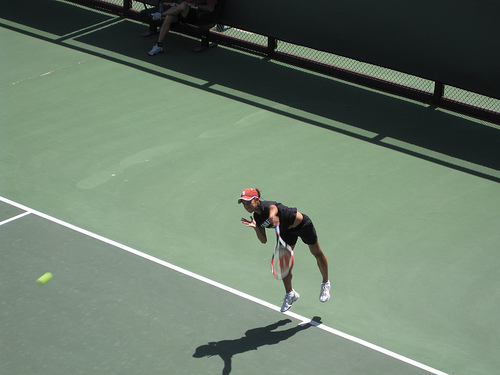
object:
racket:
[270, 226, 294, 279]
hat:
[238, 188, 258, 203]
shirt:
[253, 201, 297, 229]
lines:
[0, 195, 447, 375]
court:
[0, 81, 499, 373]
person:
[146, 2, 210, 56]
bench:
[140, 9, 217, 53]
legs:
[158, 14, 172, 43]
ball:
[35, 272, 52, 284]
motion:
[69, 255, 132, 280]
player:
[237, 188, 329, 312]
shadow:
[191, 40, 396, 88]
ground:
[0, 128, 499, 291]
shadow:
[192, 316, 324, 374]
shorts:
[280, 214, 317, 245]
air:
[51, 225, 108, 272]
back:
[6, 0, 500, 78]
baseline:
[30, 210, 182, 273]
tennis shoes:
[319, 281, 330, 302]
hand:
[269, 216, 278, 226]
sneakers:
[281, 291, 299, 312]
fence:
[0, 0, 497, 126]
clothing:
[254, 201, 316, 244]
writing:
[260, 218, 271, 227]